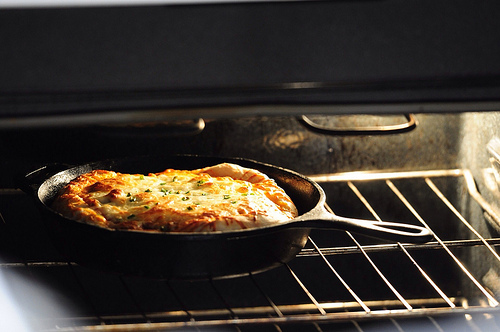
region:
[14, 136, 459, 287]
The food is being cooked.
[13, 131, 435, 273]
The pan is black.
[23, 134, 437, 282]
The pan is made of metal.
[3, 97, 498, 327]
The pan is in the oven.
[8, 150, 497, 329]
The pan is on a rack.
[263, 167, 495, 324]
The rack is made of wire.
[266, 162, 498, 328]
The rack is gray.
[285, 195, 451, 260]
The pan has a handle.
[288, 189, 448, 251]
The handle is made of metal.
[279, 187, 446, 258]
The handle is black.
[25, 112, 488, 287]
a pizza in the oven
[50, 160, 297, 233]
a pizza in the pan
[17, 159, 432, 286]
a cast iron stove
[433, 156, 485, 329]
the rack in the oven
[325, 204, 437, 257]
the handle of the pan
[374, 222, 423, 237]
a hole in the handle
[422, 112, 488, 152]
light on the stove wall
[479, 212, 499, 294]
the shelf for the rack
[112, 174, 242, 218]
green onion on the pizza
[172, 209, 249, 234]
cheese melted on the crust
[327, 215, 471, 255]
handle of the pan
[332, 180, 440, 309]
racks in the oven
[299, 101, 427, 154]
element in the oven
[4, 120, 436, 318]
food in the pan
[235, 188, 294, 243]
bread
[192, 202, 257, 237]
melted cheese over bread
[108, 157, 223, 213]
green garnish on the dish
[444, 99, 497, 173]
light from the oven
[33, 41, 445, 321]
a pan of food going into the oven to cook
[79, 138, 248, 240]
melting cheese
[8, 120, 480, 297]
Pizza in a pan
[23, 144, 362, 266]
Cheese and dough in the oven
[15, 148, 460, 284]
Cast iron skillet in the oven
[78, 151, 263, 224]
Spices on the cheese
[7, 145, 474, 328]
On the top rack in the oven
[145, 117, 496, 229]
Light on in the oven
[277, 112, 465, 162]
Element for the broiler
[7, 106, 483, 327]
Boxy interior of the oven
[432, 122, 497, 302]
Grooves where you can adjust the oven racks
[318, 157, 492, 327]
Stainless steel oven racks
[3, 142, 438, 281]
THE SKILLET IS BLACK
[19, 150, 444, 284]
THIS IS A SKILLET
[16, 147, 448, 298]
THE PIZZA IS IN THE SKILLET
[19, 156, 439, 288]
THIS IS A CAST IRON SKILLET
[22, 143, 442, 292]
THE SKILLET IS INSIDE THE OVEN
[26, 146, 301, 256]
THE PIZZA HAS A THICK CRUST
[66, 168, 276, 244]
THE CHEESE IS MELTED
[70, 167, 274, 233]
THE CHEESE IS ON THE PIZZA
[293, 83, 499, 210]
THE OVEN LIGHT IS ON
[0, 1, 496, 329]
THE OVEN DOOR IS OPEN